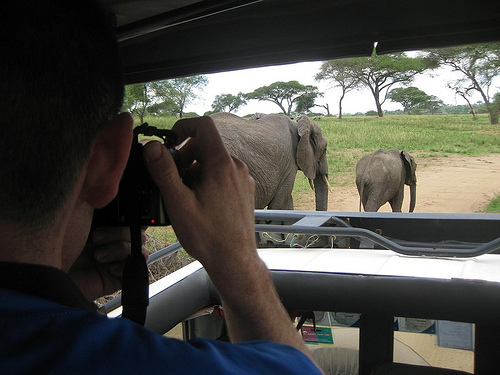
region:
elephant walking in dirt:
[341, 142, 423, 219]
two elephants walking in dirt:
[208, 90, 434, 227]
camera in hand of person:
[97, 108, 204, 251]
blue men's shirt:
[11, 248, 329, 371]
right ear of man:
[86, 95, 146, 220]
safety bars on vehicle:
[272, 200, 482, 360]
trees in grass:
[317, 60, 429, 112]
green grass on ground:
[358, 116, 397, 143]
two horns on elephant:
[300, 166, 339, 193]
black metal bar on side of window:
[332, 228, 403, 255]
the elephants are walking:
[241, 110, 425, 207]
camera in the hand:
[140, 136, 257, 238]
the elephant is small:
[344, 149, 419, 208]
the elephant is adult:
[233, 120, 337, 209]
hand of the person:
[185, 180, 256, 262]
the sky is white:
[271, 72, 304, 79]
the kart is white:
[340, 257, 380, 277]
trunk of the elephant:
[398, 178, 415, 209]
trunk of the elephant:
[314, 181, 332, 210]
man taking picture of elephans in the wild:
[45, 42, 480, 362]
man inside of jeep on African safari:
[15, 25, 480, 360]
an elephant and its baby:
[176, 105, 413, 216]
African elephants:
[191, 107, 418, 210]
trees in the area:
[98, 45, 495, 122]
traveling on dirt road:
[301, 150, 496, 215]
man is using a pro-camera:
[70, 117, 195, 239]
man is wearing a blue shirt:
[3, 252, 324, 372]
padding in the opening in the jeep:
[81, 248, 498, 373]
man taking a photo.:
[93, 107, 206, 267]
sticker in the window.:
[297, 317, 344, 356]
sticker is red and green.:
[294, 319, 334, 346]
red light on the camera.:
[142, 212, 163, 229]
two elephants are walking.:
[201, 107, 426, 207]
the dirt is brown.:
[291, 148, 497, 216]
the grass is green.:
[324, 108, 493, 178]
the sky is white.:
[181, 49, 429, 121]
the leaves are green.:
[312, 47, 439, 89]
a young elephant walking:
[348, 145, 429, 205]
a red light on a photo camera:
[151, 216, 158, 227]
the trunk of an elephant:
[408, 183, 415, 208]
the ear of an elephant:
[298, 124, 320, 177]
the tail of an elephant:
[359, 183, 369, 213]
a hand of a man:
[161, 125, 281, 326]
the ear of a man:
[96, 113, 126, 205]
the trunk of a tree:
[368, 93, 390, 120]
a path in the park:
[431, 148, 493, 206]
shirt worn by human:
[1, 278, 321, 373]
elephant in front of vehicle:
[355, 149, 419, 216]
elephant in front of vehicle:
[193, 106, 328, 211]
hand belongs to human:
[140, 111, 257, 255]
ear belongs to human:
[82, 110, 134, 212]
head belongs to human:
[2, 0, 132, 275]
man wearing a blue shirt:
[6, 54, 329, 374]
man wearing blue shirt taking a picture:
[10, 55, 320, 372]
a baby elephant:
[343, 145, 424, 214]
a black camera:
[88, 118, 198, 233]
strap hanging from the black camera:
[121, 228, 165, 328]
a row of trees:
[123, 58, 498, 128]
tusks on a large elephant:
[301, 169, 338, 199]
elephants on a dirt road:
[198, 103, 431, 216]